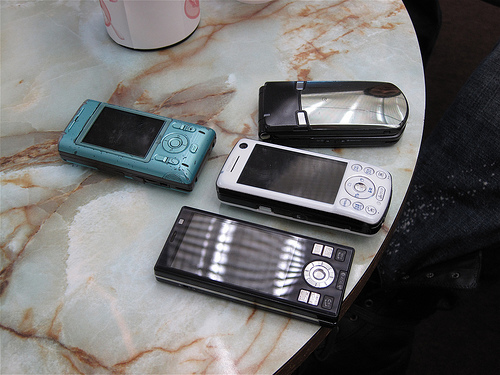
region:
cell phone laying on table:
[55, 88, 205, 178]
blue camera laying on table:
[54, 89, 206, 189]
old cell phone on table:
[61, 97, 212, 176]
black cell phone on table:
[254, 71, 404, 136]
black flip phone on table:
[251, 75, 411, 137]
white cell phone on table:
[231, 135, 403, 222]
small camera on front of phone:
[235, 137, 253, 153]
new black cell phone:
[164, 208, 359, 313]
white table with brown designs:
[0, 109, 60, 256]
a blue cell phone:
[40, 63, 265, 220]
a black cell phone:
[136, 223, 386, 335]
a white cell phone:
[219, 137, 450, 224]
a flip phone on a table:
[230, 43, 431, 165]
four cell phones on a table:
[89, 20, 420, 348]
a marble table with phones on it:
[34, 40, 362, 342]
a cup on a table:
[70, 0, 230, 65]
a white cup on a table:
[64, 0, 246, 77]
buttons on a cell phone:
[148, 83, 242, 165]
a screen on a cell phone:
[149, 203, 331, 315]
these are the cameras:
[190, 147, 382, 314]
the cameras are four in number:
[57, 58, 399, 308]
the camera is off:
[209, 230, 342, 287]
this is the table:
[51, 260, 139, 364]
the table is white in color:
[42, 227, 140, 366]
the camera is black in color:
[333, 251, 353, 274]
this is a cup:
[105, 0, 189, 45]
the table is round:
[150, 300, 247, 372]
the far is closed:
[257, 75, 404, 132]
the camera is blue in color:
[173, 120, 205, 165]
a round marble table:
[0, 0, 425, 374]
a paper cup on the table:
[96, 0, 201, 50]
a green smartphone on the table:
[57, 98, 216, 193]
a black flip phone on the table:
[257, 80, 408, 147]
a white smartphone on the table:
[215, 137, 392, 237]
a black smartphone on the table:
[153, 205, 354, 330]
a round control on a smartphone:
[302, 260, 334, 288]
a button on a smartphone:
[310, 242, 323, 255]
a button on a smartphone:
[296, 288, 311, 303]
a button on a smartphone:
[307, 292, 320, 306]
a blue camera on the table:
[53, 95, 216, 196]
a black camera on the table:
[153, 204, 355, 328]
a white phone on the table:
[216, 135, 391, 236]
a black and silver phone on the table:
[258, 79, 410, 141]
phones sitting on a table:
[3, 4, 490, 374]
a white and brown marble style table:
[1, 2, 427, 373]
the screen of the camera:
[76, 100, 171, 160]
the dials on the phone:
[343, 160, 386, 222]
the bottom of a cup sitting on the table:
[103, 1, 202, 50]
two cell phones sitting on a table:
[213, 79, 409, 236]